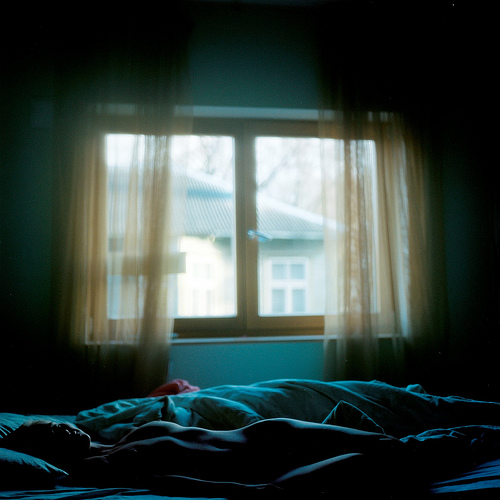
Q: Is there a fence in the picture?
A: No, there are no fences.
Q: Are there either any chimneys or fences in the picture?
A: No, there are no fences or chimneys.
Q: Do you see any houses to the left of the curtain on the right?
A: Yes, there is a house to the left of the curtain.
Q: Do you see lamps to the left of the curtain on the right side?
A: No, there is a house to the left of the curtain.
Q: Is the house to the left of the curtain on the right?
A: Yes, the house is to the left of the curtain.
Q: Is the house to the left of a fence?
A: No, the house is to the left of the curtain.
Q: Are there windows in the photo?
A: Yes, there is a window.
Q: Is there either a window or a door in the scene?
A: Yes, there is a window.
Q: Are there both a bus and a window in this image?
A: No, there is a window but no buses.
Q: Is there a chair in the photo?
A: No, there are no chairs.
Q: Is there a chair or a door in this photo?
A: No, there are no chairs or doors.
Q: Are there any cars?
A: No, there are no cars.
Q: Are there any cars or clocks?
A: No, there are no cars or clocks.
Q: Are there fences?
A: No, there are no fences.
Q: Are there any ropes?
A: No, there are no ropes.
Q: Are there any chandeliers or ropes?
A: No, there are no ropes or chandeliers.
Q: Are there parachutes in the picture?
A: No, there are no parachutes.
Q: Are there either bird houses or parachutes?
A: No, there are no parachutes or bird houses.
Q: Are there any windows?
A: Yes, there is a window.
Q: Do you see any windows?
A: Yes, there is a window.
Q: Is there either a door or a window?
A: Yes, there is a window.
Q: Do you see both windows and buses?
A: No, there is a window but no buses.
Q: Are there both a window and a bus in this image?
A: No, there is a window but no buses.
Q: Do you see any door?
A: No, there are no doors.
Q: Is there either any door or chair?
A: No, there are no doors or chairs.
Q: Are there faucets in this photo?
A: No, there are no faucets.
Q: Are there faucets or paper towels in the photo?
A: No, there are no faucets or paper towels.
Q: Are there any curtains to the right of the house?
A: Yes, there is a curtain to the right of the house.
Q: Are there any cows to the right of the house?
A: No, there is a curtain to the right of the house.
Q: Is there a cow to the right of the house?
A: No, there is a curtain to the right of the house.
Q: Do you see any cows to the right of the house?
A: No, there is a curtain to the right of the house.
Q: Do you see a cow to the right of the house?
A: No, there is a curtain to the right of the house.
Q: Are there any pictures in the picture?
A: No, there are no pictures.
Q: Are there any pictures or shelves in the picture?
A: No, there are no pictures or shelves.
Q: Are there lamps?
A: No, there are no lamps.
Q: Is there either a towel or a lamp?
A: No, there are no lamps or towels.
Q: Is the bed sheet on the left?
A: Yes, the bed sheet is on the left of the image.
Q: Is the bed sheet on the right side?
A: No, the bed sheet is on the left of the image.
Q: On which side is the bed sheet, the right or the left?
A: The bed sheet is on the left of the image.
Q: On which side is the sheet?
A: The sheet is on the left of the image.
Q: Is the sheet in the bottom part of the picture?
A: Yes, the sheet is in the bottom of the image.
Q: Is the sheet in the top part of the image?
A: No, the sheet is in the bottom of the image.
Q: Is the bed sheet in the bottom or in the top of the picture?
A: The bed sheet is in the bottom of the image.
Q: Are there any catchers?
A: No, there are no catchers.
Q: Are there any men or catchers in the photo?
A: No, there are no catchers or men.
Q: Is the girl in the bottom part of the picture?
A: Yes, the girl is in the bottom of the image.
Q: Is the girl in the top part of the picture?
A: No, the girl is in the bottom of the image.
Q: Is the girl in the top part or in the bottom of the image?
A: The girl is in the bottom of the image.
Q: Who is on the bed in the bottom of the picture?
A: The girl is on the bed.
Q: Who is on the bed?
A: The girl is on the bed.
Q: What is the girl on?
A: The girl is on the bed.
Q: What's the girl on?
A: The girl is on the bed.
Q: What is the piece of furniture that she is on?
A: The piece of furniture is a bed.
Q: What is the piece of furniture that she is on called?
A: The piece of furniture is a bed.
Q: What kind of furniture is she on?
A: The girl is on the bed.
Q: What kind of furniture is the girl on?
A: The girl is on the bed.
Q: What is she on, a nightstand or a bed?
A: The girl is on a bed.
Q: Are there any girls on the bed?
A: Yes, there is a girl on the bed.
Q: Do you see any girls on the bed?
A: Yes, there is a girl on the bed.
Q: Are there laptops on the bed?
A: No, there is a girl on the bed.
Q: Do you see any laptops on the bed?
A: No, there is a girl on the bed.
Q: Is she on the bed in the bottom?
A: Yes, the girl is on the bed.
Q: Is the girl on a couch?
A: No, the girl is on the bed.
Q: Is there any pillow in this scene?
A: Yes, there is a pillow.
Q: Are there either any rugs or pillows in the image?
A: Yes, there is a pillow.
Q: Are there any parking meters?
A: No, there are no parking meters.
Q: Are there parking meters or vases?
A: No, there are no parking meters or vases.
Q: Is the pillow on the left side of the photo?
A: Yes, the pillow is on the left of the image.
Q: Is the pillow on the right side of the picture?
A: No, the pillow is on the left of the image.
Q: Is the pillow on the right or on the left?
A: The pillow is on the left of the image.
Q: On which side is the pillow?
A: The pillow is on the left of the image.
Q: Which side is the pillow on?
A: The pillow is on the left of the image.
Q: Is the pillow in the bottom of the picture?
A: Yes, the pillow is in the bottom of the image.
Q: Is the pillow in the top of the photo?
A: No, the pillow is in the bottom of the image.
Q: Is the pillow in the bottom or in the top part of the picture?
A: The pillow is in the bottom of the image.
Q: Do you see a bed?
A: Yes, there is a bed.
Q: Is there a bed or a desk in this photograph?
A: Yes, there is a bed.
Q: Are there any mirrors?
A: No, there are no mirrors.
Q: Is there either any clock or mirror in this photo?
A: No, there are no mirrors or clocks.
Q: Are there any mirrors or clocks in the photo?
A: No, there are no mirrors or clocks.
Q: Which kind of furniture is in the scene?
A: The furniture is a bed.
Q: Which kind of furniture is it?
A: The piece of furniture is a bed.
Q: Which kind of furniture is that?
A: This is a bed.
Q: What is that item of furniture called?
A: This is a bed.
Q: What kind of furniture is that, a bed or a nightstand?
A: This is a bed.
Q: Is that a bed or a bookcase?
A: That is a bed.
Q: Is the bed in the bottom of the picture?
A: Yes, the bed is in the bottom of the image.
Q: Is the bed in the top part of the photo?
A: No, the bed is in the bottom of the image.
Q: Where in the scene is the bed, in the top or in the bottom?
A: The bed is in the bottom of the image.